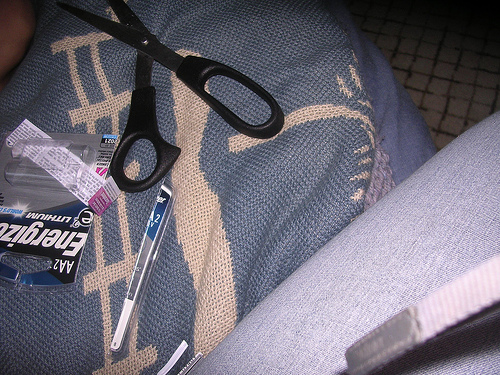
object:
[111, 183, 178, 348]
strip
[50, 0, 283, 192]
scissors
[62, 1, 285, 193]
pair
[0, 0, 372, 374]
blanket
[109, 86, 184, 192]
handle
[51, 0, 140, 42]
blades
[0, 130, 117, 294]
plastic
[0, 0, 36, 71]
skin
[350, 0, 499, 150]
floor